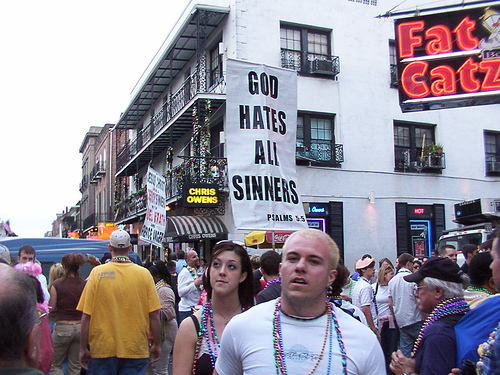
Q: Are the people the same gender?
A: No, they are both male and female.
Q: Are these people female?
A: No, they are both male and female.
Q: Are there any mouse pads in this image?
A: No, there are no mouse pads.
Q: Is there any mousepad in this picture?
A: No, there are no mouse pads.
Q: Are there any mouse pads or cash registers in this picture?
A: No, there are no mouse pads or cash registers.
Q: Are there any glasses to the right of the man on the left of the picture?
A: Yes, there are glasses to the right of the man.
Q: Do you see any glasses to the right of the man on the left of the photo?
A: Yes, there are glasses to the right of the man.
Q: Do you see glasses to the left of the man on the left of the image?
A: No, the glasses are to the right of the man.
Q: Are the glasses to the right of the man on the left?
A: Yes, the glasses are to the right of the man.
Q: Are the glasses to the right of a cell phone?
A: No, the glasses are to the right of the man.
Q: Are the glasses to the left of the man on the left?
A: No, the glasses are to the right of the man.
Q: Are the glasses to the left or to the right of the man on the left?
A: The glasses are to the right of the man.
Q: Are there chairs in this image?
A: No, there are no chairs.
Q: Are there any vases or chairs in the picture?
A: No, there are no chairs or vases.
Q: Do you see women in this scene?
A: Yes, there is a woman.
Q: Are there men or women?
A: Yes, there is a woman.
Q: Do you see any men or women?
A: Yes, there is a woman.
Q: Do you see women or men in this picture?
A: Yes, there is a woman.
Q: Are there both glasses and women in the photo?
A: Yes, there are both a woman and glasses.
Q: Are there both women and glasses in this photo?
A: Yes, there are both a woman and glasses.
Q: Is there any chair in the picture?
A: No, there are no chairs.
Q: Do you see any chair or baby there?
A: No, there are no chairs or babies.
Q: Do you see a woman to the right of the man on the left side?
A: Yes, there is a woman to the right of the man.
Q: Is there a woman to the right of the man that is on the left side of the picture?
A: Yes, there is a woman to the right of the man.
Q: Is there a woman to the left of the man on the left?
A: No, the woman is to the right of the man.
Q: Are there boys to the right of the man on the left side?
A: No, there is a woman to the right of the man.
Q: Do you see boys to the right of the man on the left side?
A: No, there is a woman to the right of the man.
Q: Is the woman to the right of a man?
A: Yes, the woman is to the right of a man.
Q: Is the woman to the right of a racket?
A: No, the woman is to the right of a man.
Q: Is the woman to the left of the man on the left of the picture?
A: No, the woman is to the right of the man.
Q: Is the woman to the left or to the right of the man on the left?
A: The woman is to the right of the man.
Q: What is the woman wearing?
A: The woman is wearing beads.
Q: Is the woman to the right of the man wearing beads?
A: Yes, the woman is wearing beads.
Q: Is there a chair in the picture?
A: No, there are no chairs.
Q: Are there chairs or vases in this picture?
A: No, there are no chairs or vases.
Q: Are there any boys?
A: No, there are no boys.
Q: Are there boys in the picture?
A: No, there are no boys.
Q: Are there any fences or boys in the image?
A: No, there are no boys or fences.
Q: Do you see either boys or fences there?
A: No, there are no boys or fences.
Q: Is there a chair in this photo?
A: No, there are no chairs.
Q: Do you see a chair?
A: No, there are no chairs.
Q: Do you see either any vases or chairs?
A: No, there are no chairs or vases.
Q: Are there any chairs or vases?
A: No, there are no chairs or vases.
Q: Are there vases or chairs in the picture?
A: No, there are no chairs or vases.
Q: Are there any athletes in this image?
A: No, there are no athletes.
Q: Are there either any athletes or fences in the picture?
A: No, there are no athletes or fences.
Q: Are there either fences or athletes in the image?
A: No, there are no athletes or fences.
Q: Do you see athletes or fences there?
A: No, there are no athletes or fences.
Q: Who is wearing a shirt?
A: The man is wearing a shirt.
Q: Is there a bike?
A: No, there are no bikes.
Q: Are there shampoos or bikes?
A: No, there are no bikes or shampoos.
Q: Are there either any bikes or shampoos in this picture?
A: No, there are no bikes or shampoos.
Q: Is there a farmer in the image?
A: No, there are no farmers.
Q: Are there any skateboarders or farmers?
A: No, there are no farmers or skateboarders.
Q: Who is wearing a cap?
A: The man is wearing a cap.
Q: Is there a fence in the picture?
A: No, there are no fences.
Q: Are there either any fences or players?
A: No, there are no fences or players.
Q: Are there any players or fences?
A: No, there are no fences or players.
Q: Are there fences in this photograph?
A: No, there are no fences.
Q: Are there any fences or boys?
A: No, there are no fences or boys.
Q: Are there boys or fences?
A: No, there are no fences or boys.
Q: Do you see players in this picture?
A: No, there are no players.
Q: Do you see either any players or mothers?
A: No, there are no players or mothers.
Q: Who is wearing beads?
A: The man is wearing beads.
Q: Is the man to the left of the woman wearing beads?
A: Yes, the man is wearing beads.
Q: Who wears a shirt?
A: The man wears a shirt.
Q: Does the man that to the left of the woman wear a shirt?
A: Yes, the man wears a shirt.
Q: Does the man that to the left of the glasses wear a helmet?
A: No, the man wears a shirt.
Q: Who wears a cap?
A: The man wears a cap.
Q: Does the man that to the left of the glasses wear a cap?
A: Yes, the man wears a cap.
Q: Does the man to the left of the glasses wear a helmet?
A: No, the man wears a cap.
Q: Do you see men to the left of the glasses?
A: Yes, there is a man to the left of the glasses.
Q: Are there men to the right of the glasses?
A: No, the man is to the left of the glasses.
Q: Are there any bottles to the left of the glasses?
A: No, there is a man to the left of the glasses.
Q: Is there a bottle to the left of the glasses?
A: No, there is a man to the left of the glasses.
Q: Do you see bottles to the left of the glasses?
A: No, there is a man to the left of the glasses.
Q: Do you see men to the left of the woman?
A: Yes, there is a man to the left of the woman.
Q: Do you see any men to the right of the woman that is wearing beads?
A: No, the man is to the left of the woman.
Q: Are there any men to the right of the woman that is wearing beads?
A: No, the man is to the left of the woman.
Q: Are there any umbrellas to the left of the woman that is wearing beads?
A: No, there is a man to the left of the woman.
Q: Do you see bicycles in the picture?
A: No, there are no bicycles.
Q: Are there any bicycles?
A: No, there are no bicycles.